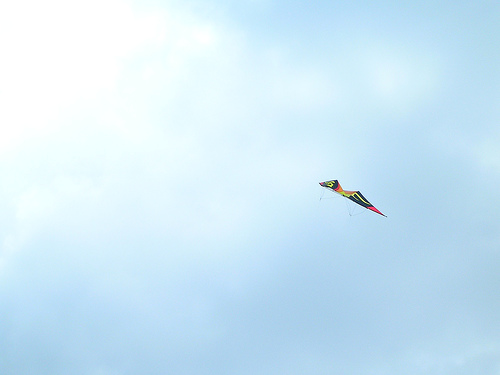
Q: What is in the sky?
A: Kite.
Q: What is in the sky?
A: Kite.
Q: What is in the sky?
A: Sun.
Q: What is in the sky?
A: Clouds.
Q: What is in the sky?
A: Clouds.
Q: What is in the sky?
A: Sun.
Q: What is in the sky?
A: Sun.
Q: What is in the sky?
A: Sun.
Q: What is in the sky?
A: Kite.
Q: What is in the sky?
A: Sun.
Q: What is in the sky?
A: Kite.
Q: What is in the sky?
A: Kite.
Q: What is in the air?
A: Kite.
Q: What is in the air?
A: Clouds.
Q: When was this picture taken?
A: Daytime.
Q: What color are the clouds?
A: White.